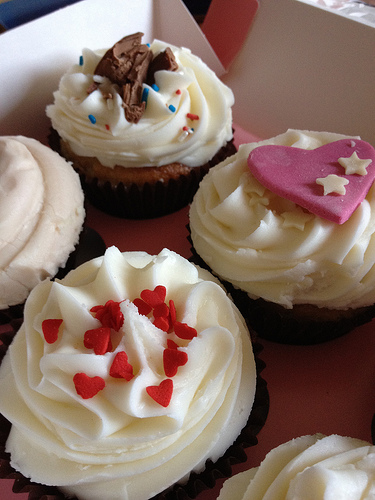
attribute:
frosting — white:
[0, 129, 94, 263]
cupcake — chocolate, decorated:
[2, 245, 275, 494]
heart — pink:
[256, 131, 369, 242]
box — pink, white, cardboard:
[150, 1, 373, 84]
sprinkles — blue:
[78, 40, 200, 128]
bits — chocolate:
[74, 30, 186, 123]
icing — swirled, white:
[23, 255, 236, 479]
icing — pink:
[2, 134, 65, 278]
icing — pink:
[187, 207, 370, 286]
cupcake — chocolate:
[45, 30, 219, 191]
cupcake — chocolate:
[187, 122, 374, 315]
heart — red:
[162, 346, 187, 376]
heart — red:
[73, 371, 106, 399]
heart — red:
[109, 350, 134, 378]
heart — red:
[40, 318, 63, 342]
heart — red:
[139, 285, 167, 306]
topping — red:
[84, 326, 110, 352]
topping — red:
[36, 287, 201, 415]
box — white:
[4, 6, 362, 163]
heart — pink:
[250, 138, 372, 229]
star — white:
[314, 171, 352, 196]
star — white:
[337, 151, 369, 179]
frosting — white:
[2, 243, 258, 497]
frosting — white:
[217, 429, 373, 498]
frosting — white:
[192, 129, 373, 315]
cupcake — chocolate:
[45, 27, 239, 223]